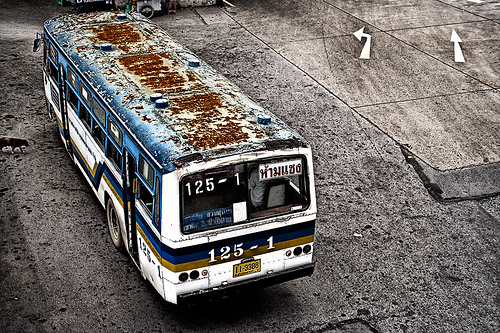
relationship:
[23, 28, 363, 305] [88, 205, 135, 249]
bus has wheel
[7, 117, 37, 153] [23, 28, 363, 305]
animal near bus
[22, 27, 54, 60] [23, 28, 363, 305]
mirror on bus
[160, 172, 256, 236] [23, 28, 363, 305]
window on bus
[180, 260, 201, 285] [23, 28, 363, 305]
lights on bus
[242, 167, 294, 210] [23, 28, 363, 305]
person seated in bus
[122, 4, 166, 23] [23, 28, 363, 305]
road sign outside bus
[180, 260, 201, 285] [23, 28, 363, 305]
lights on back of bus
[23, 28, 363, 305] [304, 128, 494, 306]
bus on road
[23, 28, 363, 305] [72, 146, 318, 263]
bus has stripes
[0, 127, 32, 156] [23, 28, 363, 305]
animal near bus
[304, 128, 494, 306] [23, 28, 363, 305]
road near bus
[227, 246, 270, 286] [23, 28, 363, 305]
license on rear of bus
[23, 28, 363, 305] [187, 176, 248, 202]
bus has numbers